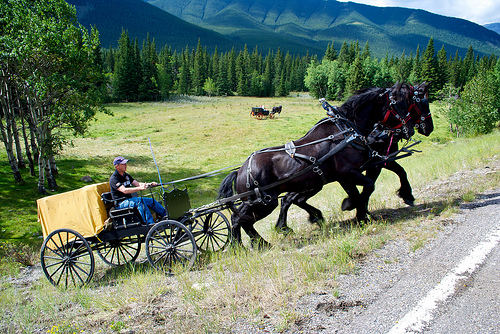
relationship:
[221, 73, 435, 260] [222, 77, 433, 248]
pair of horses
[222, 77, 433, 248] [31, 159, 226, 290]
horses pulling carriage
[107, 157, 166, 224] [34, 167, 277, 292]
man sitting on wagon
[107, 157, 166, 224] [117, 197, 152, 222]
man in blue jeans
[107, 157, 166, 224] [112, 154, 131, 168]
man in cap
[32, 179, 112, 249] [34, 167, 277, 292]
box on wagon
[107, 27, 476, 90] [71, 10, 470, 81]
trees in background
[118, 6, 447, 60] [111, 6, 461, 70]
range in distance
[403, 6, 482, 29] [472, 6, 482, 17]
sky with clouds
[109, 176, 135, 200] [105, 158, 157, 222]
shirt on man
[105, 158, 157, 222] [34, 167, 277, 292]
man in wagon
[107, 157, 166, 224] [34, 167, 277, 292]
man in wagon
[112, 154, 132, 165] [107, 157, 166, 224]
cap on man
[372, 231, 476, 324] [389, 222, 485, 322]
edge of road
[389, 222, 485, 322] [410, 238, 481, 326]
road with line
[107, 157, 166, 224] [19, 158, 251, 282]
man on carriage